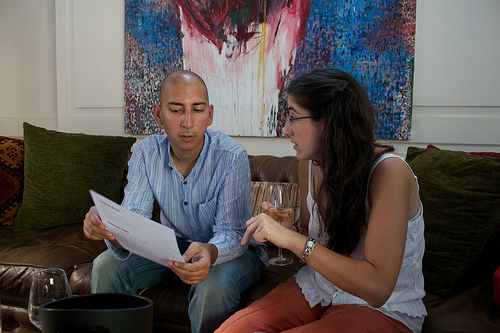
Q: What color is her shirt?
A: White.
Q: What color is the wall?
A: White.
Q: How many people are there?
A: Two.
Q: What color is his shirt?
A: Blue.